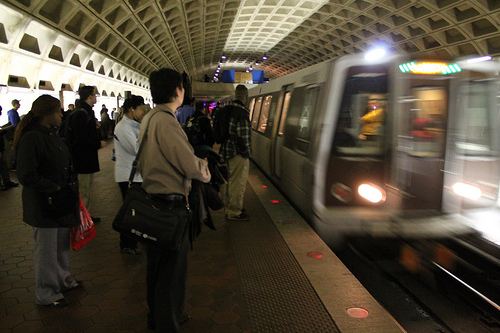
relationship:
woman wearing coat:
[11, 95, 82, 307] [17, 124, 88, 220]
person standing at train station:
[126, 67, 211, 330] [7, 2, 498, 328]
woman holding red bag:
[11, 95, 82, 307] [74, 192, 98, 252]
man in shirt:
[218, 83, 254, 220] [211, 100, 255, 165]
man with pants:
[218, 83, 254, 220] [212, 150, 251, 219]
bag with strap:
[116, 115, 188, 249] [131, 137, 145, 167]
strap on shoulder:
[131, 137, 145, 167] [153, 104, 177, 132]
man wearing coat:
[127, 63, 214, 331] [136, 108, 210, 192]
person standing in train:
[126, 67, 211, 330] [272, 79, 488, 189]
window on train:
[410, 86, 445, 160] [245, 47, 490, 246]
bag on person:
[116, 115, 188, 249] [126, 67, 211, 330]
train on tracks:
[245, 47, 490, 246] [380, 234, 499, 329]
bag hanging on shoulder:
[106, 110, 161, 238] [153, 104, 177, 132]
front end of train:
[322, 51, 499, 238] [215, 54, 499, 237]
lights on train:
[245, 50, 497, 254] [353, 178, 396, 203]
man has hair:
[127, 63, 214, 331] [147, 62, 191, 109]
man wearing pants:
[127, 63, 214, 331] [140, 192, 195, 330]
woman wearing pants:
[11, 95, 82, 307] [32, 217, 76, 308]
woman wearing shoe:
[11, 95, 82, 307] [37, 295, 68, 306]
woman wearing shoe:
[11, 95, 82, 307] [67, 281, 81, 291]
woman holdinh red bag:
[11, 95, 82, 307] [51, 166, 116, 270]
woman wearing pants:
[11, 95, 82, 307] [31, 225, 76, 305]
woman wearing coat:
[11, 95, 82, 307] [13, 124, 82, 229]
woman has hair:
[11, 95, 82, 307] [8, 92, 61, 182]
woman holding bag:
[11, 95, 82, 307] [67, 194, 100, 249]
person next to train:
[126, 67, 211, 330] [245, 47, 490, 246]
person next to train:
[9, 92, 90, 312] [245, 47, 490, 246]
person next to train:
[109, 93, 146, 261] [245, 47, 490, 246]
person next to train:
[217, 77, 259, 225] [245, 47, 490, 246]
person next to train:
[97, 110, 113, 154] [245, 47, 490, 246]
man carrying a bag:
[127, 63, 214, 331] [189, 145, 216, 187]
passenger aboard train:
[358, 95, 383, 140] [245, 47, 490, 246]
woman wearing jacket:
[11, 95, 82, 307] [24, 130, 76, 240]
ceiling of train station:
[16, 1, 498, 75] [7, 2, 498, 328]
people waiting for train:
[12, 61, 297, 321] [245, 47, 490, 246]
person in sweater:
[126, 67, 211, 330] [132, 104, 214, 195]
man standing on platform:
[127, 63, 214, 331] [3, 127, 394, 326]